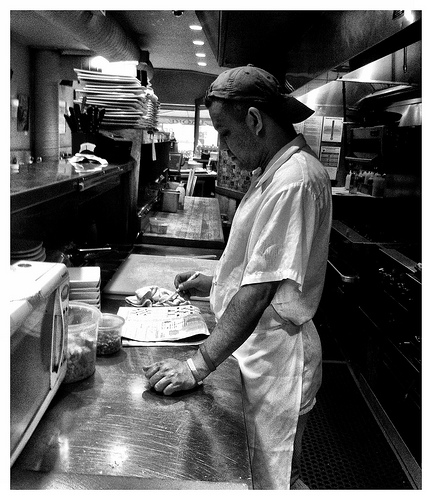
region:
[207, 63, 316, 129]
baseball cap worn backwards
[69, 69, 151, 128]
stack of empty trays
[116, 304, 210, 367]
folded page of newspaper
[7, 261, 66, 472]
microwave oven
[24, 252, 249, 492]
aluminum food prep counter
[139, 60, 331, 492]
food service worker wearing dark cap, white shirt, and white apron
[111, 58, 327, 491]
food service worker writing newspaper with marker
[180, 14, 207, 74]
overhead lighting fixtures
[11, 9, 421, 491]
food service worker in large commercial kitchen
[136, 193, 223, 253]
wooden food prep chopping block table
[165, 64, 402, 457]
this is a man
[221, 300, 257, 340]
the man is light skinned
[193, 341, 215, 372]
this is a wrist band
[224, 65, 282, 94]
this is a cap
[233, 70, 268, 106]
the cap is black in color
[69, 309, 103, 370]
this is a tin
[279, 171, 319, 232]
this is a shirt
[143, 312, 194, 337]
this is a paper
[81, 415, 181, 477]
this is a table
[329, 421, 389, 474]
this is the ground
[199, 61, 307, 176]
a man wearing a hat backwards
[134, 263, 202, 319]
a man holding a pen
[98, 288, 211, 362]
a newspaper on a counter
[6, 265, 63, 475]
a microwave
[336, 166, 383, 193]
several plastic bottles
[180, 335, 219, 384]
a man wearing two wrist bands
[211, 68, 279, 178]
a man looking down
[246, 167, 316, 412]
a man wearing a apron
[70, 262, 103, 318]
a stack of dinner plates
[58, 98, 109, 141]
several knives in a container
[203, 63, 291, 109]
it is a hat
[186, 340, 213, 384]
the man is wearing wrist bands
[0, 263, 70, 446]
it is a white microwave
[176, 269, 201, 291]
man has a marker in his hand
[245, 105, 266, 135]
it is the ear of the man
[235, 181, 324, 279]
the man is wearing a white shirt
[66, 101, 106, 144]
knifes sitting on the shelf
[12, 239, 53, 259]
plates in the background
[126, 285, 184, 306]
a white cloth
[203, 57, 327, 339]
a chef is in the kitchen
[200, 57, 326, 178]
the head of a man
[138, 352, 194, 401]
the hand of a man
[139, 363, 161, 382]
the finger of a man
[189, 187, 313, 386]
the arm of a man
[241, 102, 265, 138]
the ear of a man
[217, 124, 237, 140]
the eye of a man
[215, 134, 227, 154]
the nose of a man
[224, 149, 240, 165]
the mouth of a man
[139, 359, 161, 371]
the thumb of a man